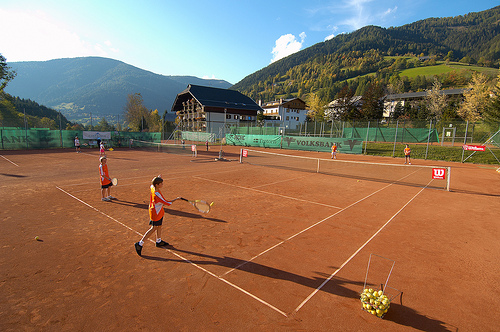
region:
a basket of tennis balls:
[343, 250, 425, 315]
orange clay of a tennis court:
[421, 210, 486, 300]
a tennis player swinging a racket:
[138, 182, 228, 254]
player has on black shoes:
[118, 230, 208, 260]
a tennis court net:
[251, 142, 453, 196]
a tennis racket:
[171, 190, 233, 217]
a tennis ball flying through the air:
[206, 192, 228, 214]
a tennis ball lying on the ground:
[21, 217, 53, 262]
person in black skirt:
[78, 157, 123, 209]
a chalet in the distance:
[133, 88, 278, 158]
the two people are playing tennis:
[73, 143, 219, 267]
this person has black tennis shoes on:
[133, 175, 184, 270]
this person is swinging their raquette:
[126, 160, 227, 268]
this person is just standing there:
[83, 140, 126, 217]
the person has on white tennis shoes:
[82, 151, 122, 221]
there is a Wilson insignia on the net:
[406, 150, 458, 186]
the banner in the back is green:
[218, 124, 381, 161]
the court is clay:
[48, 269, 125, 324]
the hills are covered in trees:
[321, 42, 397, 69]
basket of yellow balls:
[348, 256, 420, 329]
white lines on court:
[183, 258, 309, 316]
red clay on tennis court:
[17, 235, 132, 304]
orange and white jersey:
[137, 190, 180, 222]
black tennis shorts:
[126, 217, 203, 238]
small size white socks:
[118, 221, 177, 246]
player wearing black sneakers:
[134, 240, 194, 258]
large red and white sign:
[423, 154, 464, 202]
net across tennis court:
[208, 148, 474, 208]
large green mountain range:
[243, 9, 428, 94]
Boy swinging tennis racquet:
[129, 171, 214, 263]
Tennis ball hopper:
[356, 249, 404, 323]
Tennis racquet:
[172, 189, 218, 220]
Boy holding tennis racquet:
[89, 151, 124, 207]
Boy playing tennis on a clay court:
[128, 171, 218, 266]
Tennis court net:
[234, 144, 459, 205]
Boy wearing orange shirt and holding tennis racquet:
[91, 153, 122, 207]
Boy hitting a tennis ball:
[128, 171, 220, 265]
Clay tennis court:
[52, 139, 449, 321]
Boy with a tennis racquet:
[93, 154, 120, 209]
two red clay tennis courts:
[0, 133, 496, 326]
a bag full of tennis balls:
[357, 255, 405, 320]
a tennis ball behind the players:
[27, 230, 47, 248]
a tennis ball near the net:
[350, 173, 361, 185]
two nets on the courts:
[123, 135, 449, 196]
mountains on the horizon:
[2, 51, 240, 157]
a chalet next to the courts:
[166, 81, 261, 144]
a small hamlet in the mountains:
[145, 90, 496, 155]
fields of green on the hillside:
[267, 48, 497, 114]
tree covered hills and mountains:
[236, 8, 498, 130]